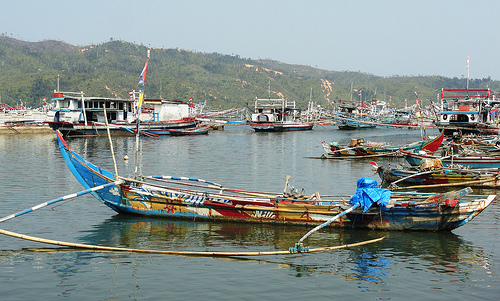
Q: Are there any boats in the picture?
A: Yes, there is a boat.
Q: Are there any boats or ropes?
A: Yes, there is a boat.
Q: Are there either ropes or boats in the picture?
A: Yes, there is a boat.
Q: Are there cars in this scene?
A: No, there are no cars.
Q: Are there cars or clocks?
A: No, there are no cars or clocks.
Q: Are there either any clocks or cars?
A: No, there are no cars or clocks.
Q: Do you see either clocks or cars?
A: No, there are no cars or clocks.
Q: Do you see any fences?
A: No, there are no fences.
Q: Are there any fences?
A: No, there are no fences.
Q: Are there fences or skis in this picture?
A: No, there are no fences or skis.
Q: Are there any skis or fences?
A: No, there are no fences or skis.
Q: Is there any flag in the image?
A: Yes, there is a flag.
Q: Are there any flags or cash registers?
A: Yes, there is a flag.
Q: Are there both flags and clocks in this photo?
A: No, there is a flag but no clocks.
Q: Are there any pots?
A: No, there are no pots.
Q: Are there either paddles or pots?
A: No, there are no pots or paddles.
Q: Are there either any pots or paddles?
A: No, there are no pots or paddles.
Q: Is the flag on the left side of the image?
A: Yes, the flag is on the left of the image.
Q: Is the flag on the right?
A: No, the flag is on the left of the image.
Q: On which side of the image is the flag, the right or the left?
A: The flag is on the left of the image.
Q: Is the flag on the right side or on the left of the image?
A: The flag is on the left of the image.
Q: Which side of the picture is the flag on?
A: The flag is on the left of the image.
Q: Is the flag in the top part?
A: Yes, the flag is in the top of the image.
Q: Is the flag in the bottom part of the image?
A: No, the flag is in the top of the image.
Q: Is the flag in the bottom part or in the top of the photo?
A: The flag is in the top of the image.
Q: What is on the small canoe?
A: The flag is on the canoe.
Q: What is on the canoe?
A: The flag is on the canoe.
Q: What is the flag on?
A: The flag is on the canoe.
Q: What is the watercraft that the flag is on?
A: The watercraft is a canoe.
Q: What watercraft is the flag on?
A: The flag is on the kayak.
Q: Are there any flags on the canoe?
A: Yes, there is a flag on the canoe.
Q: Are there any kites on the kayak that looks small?
A: No, there is a flag on the kayak.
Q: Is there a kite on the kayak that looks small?
A: No, there is a flag on the kayak.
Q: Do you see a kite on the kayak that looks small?
A: No, there is a flag on the kayak.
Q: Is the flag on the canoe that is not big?
A: Yes, the flag is on the canoe.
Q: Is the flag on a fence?
A: No, the flag is on the canoe.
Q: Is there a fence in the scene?
A: No, there are no fences.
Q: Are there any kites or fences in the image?
A: No, there are no fences or kites.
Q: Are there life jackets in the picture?
A: No, there are no life jackets.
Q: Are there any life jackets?
A: No, there are no life jackets.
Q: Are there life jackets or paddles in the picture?
A: No, there are no life jackets or paddles.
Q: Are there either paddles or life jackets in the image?
A: No, there are no life jackets or paddles.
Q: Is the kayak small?
A: Yes, the kayak is small.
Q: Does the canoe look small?
A: Yes, the canoe is small.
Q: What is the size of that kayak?
A: The kayak is small.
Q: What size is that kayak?
A: The kayak is small.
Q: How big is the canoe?
A: The canoe is small.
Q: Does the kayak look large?
A: No, the kayak is small.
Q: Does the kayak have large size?
A: No, the kayak is small.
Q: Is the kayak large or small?
A: The kayak is small.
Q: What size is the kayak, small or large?
A: The kayak is small.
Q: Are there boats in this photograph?
A: Yes, there is a boat.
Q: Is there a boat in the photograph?
A: Yes, there is a boat.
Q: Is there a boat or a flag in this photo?
A: Yes, there is a boat.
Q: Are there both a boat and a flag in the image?
A: Yes, there are both a boat and a flag.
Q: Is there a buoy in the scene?
A: No, there are no buoys.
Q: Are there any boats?
A: Yes, there is a boat.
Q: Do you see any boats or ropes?
A: Yes, there is a boat.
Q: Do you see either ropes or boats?
A: Yes, there is a boat.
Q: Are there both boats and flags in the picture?
A: Yes, there are both a boat and a flag.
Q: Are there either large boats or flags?
A: Yes, there is a large boat.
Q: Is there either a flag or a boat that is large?
A: Yes, the boat is large.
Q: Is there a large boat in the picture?
A: Yes, there is a large boat.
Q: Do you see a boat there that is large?
A: Yes, there is a boat that is large.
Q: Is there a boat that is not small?
A: Yes, there is a large boat.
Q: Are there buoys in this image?
A: No, there are no buoys.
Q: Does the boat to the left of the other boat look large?
A: Yes, the boat is large.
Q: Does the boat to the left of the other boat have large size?
A: Yes, the boat is large.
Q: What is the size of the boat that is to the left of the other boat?
A: The boat is large.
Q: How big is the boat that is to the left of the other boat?
A: The boat is large.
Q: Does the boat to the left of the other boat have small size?
A: No, the boat is large.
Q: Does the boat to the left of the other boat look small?
A: No, the boat is large.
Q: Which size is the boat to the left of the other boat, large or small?
A: The boat is large.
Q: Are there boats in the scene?
A: Yes, there is a boat.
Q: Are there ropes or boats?
A: Yes, there is a boat.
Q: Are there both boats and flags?
A: Yes, there are both a boat and a flag.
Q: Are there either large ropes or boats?
A: Yes, there is a large boat.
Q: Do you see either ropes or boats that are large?
A: Yes, the boat is large.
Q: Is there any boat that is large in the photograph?
A: Yes, there is a large boat.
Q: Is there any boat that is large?
A: Yes, there is a boat that is large.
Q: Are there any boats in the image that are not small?
A: Yes, there is a large boat.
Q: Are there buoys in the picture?
A: No, there are no buoys.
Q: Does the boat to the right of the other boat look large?
A: Yes, the boat is large.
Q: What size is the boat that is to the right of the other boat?
A: The boat is large.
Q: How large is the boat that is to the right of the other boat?
A: The boat is large.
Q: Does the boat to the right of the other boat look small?
A: No, the boat is large.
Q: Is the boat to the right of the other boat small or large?
A: The boat is large.